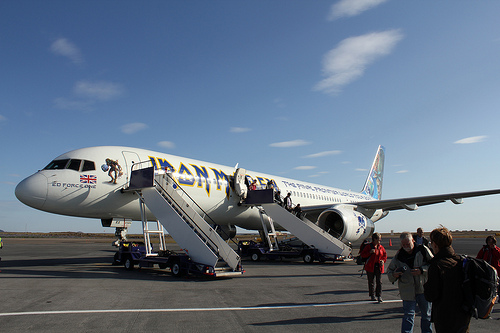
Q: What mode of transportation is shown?
A: Plane.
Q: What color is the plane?
A: White.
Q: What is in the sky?
A: Clouds.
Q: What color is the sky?
A: Blue.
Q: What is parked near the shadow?
A: Airplane.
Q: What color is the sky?
A: Blue.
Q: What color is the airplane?
A: White.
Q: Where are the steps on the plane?
A: In front on the side.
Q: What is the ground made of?
A: Pavement.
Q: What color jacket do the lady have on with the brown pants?
A: Red.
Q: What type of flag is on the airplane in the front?
A: Great Britain.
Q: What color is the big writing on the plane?
A: Blue and yellow.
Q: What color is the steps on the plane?
A: White.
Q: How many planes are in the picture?
A: 1.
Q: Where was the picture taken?
A: At an airport.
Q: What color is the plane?
A: White.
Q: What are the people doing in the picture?
A: Getting off the plane.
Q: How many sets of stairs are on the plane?
A: 2.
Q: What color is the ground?
A: Black.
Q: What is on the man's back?
A: A backpack.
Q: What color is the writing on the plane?
A: Blue.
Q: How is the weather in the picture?
A: Sunny.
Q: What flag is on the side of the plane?
A: British flag.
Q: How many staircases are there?
A: Two.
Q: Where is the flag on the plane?
A: In the front?.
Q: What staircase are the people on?
A: Right.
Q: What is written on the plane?
A: Ironmaiden.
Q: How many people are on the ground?
A: Five.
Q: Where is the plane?
A: The runway.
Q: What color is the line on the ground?
A: White.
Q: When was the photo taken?
A: Daytime.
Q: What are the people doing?
A: Disembarking.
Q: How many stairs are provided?
A: Two sets.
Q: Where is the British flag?
A: Under the cockpit window.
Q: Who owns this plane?
A: The band Iron Maiden.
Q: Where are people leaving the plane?
A: From the second door.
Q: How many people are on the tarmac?
A: Five.